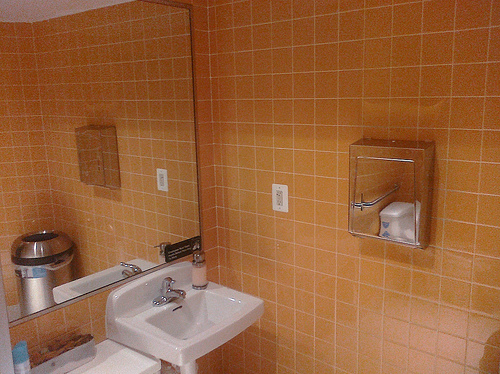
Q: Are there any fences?
A: No, there are no fences.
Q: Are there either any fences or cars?
A: No, there are no fences or cars.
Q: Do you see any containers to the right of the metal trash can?
A: Yes, there is a container to the right of the garbage can.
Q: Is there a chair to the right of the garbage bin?
A: No, there is a container to the right of the garbage bin.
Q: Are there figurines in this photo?
A: No, there are no figurines.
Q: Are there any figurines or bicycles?
A: No, there are no figurines or bicycles.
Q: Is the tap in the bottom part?
A: Yes, the tap is in the bottom of the image.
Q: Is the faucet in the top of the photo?
A: No, the faucet is in the bottom of the image.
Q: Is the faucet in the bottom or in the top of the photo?
A: The faucet is in the bottom of the image.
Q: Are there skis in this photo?
A: No, there are no skis.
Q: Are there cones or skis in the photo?
A: No, there are no skis or cones.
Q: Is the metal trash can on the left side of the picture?
A: Yes, the garbage can is on the left of the image.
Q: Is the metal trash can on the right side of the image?
A: No, the garbage can is on the left of the image.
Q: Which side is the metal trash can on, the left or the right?
A: The trash bin is on the left of the image.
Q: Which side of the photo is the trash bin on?
A: The trash bin is on the left of the image.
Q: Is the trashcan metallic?
A: Yes, the trashcan is metallic.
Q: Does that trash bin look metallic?
A: Yes, the trash bin is metallic.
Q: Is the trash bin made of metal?
A: Yes, the trash bin is made of metal.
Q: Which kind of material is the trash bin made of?
A: The trash bin is made of metal.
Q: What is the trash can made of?
A: The trash bin is made of metal.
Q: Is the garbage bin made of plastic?
A: No, the garbage bin is made of metal.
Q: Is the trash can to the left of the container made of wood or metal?
A: The garbage bin is made of metal.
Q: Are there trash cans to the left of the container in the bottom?
A: Yes, there is a trash can to the left of the container.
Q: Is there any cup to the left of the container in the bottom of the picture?
A: No, there is a trash can to the left of the container.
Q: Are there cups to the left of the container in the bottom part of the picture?
A: No, there is a trash can to the left of the container.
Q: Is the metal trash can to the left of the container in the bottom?
A: Yes, the garbage can is to the left of the container.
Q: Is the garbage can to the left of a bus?
A: No, the garbage can is to the left of the container.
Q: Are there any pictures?
A: No, there are no pictures.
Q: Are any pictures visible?
A: No, there are no pictures.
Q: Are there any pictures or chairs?
A: No, there are no pictures or chairs.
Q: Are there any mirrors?
A: Yes, there is a mirror.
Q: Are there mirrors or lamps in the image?
A: Yes, there is a mirror.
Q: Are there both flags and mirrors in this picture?
A: No, there is a mirror but no flags.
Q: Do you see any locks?
A: No, there are no locks.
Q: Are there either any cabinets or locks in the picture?
A: No, there are no locks or cabinets.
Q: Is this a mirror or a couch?
A: This is a mirror.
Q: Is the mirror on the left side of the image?
A: Yes, the mirror is on the left of the image.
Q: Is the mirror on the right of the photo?
A: No, the mirror is on the left of the image.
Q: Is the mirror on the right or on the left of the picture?
A: The mirror is on the left of the image.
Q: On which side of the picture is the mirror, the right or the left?
A: The mirror is on the left of the image.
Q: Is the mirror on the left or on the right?
A: The mirror is on the left of the image.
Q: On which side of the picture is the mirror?
A: The mirror is on the left of the image.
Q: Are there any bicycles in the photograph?
A: No, there are no bicycles.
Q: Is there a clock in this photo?
A: No, there are no clocks.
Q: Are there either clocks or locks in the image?
A: No, there are no clocks or locks.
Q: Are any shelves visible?
A: No, there are no shelves.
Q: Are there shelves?
A: No, there are no shelves.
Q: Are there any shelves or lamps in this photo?
A: No, there are no shelves or lamps.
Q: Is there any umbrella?
A: Yes, there are umbrellas.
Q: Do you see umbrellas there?
A: Yes, there are umbrellas.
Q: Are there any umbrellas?
A: Yes, there are umbrellas.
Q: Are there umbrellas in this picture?
A: Yes, there are umbrellas.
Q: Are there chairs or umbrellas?
A: Yes, there are umbrellas.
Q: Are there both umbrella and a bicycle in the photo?
A: No, there are umbrellas but no bicycles.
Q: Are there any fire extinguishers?
A: No, there are no fire extinguishers.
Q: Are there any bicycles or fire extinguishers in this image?
A: No, there are no fire extinguishers or bicycles.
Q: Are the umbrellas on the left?
A: Yes, the umbrellas are on the left of the image.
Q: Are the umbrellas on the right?
A: No, the umbrellas are on the left of the image.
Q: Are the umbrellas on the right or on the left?
A: The umbrellas are on the left of the image.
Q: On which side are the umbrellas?
A: The umbrellas are on the left of the image.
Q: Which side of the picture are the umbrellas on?
A: The umbrellas are on the left of the image.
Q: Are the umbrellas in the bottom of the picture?
A: Yes, the umbrellas are in the bottom of the image.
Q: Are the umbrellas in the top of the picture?
A: No, the umbrellas are in the bottom of the image.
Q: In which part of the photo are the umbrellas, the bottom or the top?
A: The umbrellas are in the bottom of the image.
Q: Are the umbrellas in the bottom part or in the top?
A: The umbrellas are in the bottom of the image.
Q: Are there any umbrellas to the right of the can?
A: Yes, there are umbrellas to the right of the can.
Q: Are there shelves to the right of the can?
A: No, there are umbrellas to the right of the can.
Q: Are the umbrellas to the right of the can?
A: Yes, the umbrellas are to the right of the can.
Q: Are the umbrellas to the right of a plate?
A: No, the umbrellas are to the right of the can.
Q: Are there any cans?
A: Yes, there is a can.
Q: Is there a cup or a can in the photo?
A: Yes, there is a can.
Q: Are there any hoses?
A: No, there are no hoses.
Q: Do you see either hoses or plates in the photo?
A: No, there are no hoses or plates.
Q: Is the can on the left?
A: Yes, the can is on the left of the image.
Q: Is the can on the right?
A: No, the can is on the left of the image.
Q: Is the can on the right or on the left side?
A: The can is on the left of the image.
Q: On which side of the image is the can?
A: The can is on the left of the image.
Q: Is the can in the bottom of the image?
A: Yes, the can is in the bottom of the image.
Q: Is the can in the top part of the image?
A: No, the can is in the bottom of the image.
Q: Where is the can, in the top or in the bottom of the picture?
A: The can is in the bottom of the image.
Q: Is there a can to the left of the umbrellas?
A: Yes, there is a can to the left of the umbrellas.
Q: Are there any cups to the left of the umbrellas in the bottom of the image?
A: No, there is a can to the left of the umbrellas.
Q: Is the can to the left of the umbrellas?
A: Yes, the can is to the left of the umbrellas.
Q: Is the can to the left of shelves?
A: No, the can is to the left of the umbrellas.